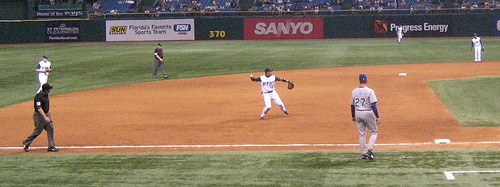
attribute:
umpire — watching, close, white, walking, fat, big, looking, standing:
[20, 77, 63, 166]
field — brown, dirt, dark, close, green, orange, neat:
[95, 44, 248, 180]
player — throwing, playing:
[244, 69, 304, 119]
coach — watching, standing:
[345, 71, 392, 165]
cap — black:
[38, 81, 54, 95]